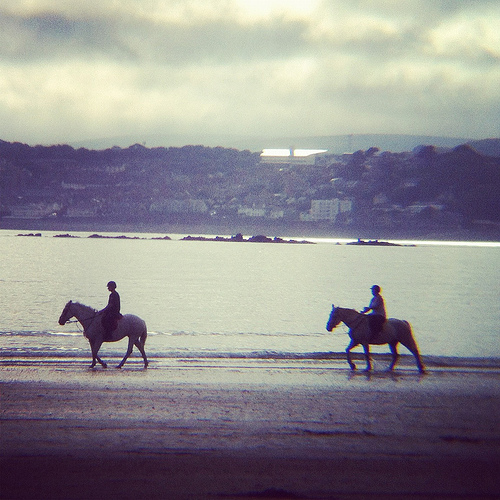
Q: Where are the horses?
A: The beach.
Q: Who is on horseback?
A: Two people.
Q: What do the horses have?
A: Riders.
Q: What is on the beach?
A: Sand.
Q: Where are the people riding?
A: On the beach.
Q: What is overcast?
A: Sky.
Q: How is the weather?
A: Cloudy.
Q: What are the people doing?
A: Riding horses.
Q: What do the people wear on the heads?
A: Helmets.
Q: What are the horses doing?
A: Walking in the water.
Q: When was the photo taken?
A: Daytime.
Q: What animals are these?
A: Horses.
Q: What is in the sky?
A: Clouds.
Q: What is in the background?
A: A city.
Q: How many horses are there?
A: Two.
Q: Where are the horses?
A: On the beach.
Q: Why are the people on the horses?
A: To take a ride.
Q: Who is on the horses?
A: Two people.